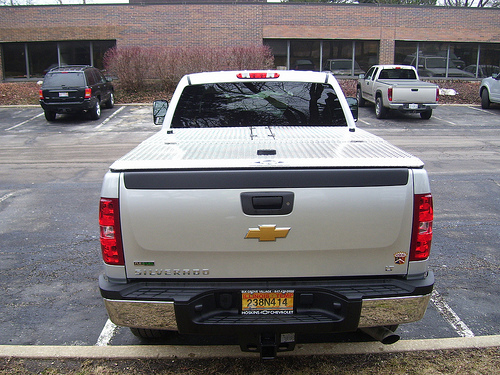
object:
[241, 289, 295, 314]
license plate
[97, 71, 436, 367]
truck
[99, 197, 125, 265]
tail light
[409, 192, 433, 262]
tail light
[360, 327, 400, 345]
exhaust pipe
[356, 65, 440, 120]
truck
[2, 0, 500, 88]
building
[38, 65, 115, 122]
car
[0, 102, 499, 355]
parking lot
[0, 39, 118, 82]
windows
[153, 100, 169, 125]
side mirror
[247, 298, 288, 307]
number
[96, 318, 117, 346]
line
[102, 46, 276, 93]
bushes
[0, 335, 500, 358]
curb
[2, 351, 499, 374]
grass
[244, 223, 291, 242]
chevrolet logo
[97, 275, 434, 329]
bumper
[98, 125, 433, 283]
flatbed